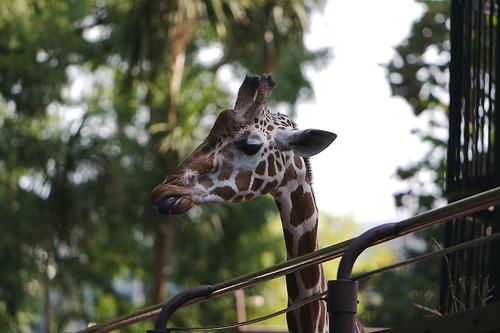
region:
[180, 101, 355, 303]
giraffe has long neck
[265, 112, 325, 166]
giraffe has grey ears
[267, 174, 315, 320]
white and brown spots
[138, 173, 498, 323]
green leaf in front of giraffe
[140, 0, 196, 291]
tall brown trunk in background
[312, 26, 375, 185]
sky is bright grey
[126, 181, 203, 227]
giraffe has brown nose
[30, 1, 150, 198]
green leaves on trees in background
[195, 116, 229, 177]
brown strip on giraffe's face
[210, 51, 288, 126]
brown and black horns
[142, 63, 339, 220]
Top of giraffe's head.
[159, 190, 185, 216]
Tongue sticking out of giraffe.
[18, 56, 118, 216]
Group of trees in the background.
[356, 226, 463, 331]
Steel gate under giraffe.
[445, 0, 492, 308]
Bar cages next to giraffe.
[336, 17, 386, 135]
Clear sky above animal.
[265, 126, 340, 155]
Giraffe's ear sticking over gate.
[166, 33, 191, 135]
Stem of man's tree.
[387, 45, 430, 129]
Small green leaves in the back.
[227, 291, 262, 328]
Small yellow wood piece next to cage.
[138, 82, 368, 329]
a giraffe looking over a fence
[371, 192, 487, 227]
shiny grey metal rail of the fence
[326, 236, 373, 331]
black metal pole of the fence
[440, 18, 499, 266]
black iron cage behind the giraffe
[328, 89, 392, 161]
cloudy white skies over the scene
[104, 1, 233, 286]
palm tree growing inside of the pen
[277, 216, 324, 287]
brown spots on the giraffe's neck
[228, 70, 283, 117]
brown and black horn's of the giraffe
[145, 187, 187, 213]
black tongue sticking out of the giraffe's mouth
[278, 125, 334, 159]
white ear of the giraffe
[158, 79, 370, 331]
the head of a giraffe over a fence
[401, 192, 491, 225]
grey metal rail of the fence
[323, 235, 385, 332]
black metal post of the fence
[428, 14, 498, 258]
black metal fence next to the giraffe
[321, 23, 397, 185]
cloudy white skies over the scene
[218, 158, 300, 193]
brown spots on the head of the giraffe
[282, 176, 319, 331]
long neck of the giraffe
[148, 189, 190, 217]
black tongue hanging out of the giraffe's mouth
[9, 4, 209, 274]
trees growing behind the giraffe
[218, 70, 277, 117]
black and brown horns of the giraffe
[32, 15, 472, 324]
photograph of a giraffe in a zoo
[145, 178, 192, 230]
giraffes black tongue visible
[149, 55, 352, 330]
giraffes head andd neck visible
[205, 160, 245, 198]
brown spots on giraffe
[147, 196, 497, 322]
silver metal fence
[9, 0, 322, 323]
tall green trees in he background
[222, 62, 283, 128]
two horns on giraffes head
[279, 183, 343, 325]
long skinny neck of giraffe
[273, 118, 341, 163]
giraffes ear sticking out to the side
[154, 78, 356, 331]
giraffe looking over gate